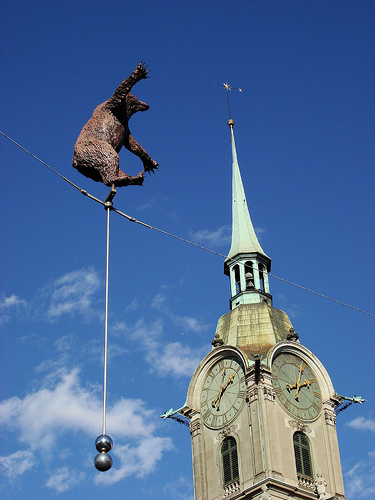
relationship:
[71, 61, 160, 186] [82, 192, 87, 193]
bear statue on wire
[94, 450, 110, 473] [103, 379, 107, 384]
ball on rod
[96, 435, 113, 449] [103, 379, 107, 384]
ball on rod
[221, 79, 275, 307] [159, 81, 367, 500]
steeple of building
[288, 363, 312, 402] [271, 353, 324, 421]
hands of clock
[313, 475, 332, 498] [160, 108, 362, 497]
statue on building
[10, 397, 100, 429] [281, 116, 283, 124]
clouds in sky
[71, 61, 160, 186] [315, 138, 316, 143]
bear statue in air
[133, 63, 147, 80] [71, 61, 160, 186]
bear paw on bear statue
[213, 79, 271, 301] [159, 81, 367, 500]
steeple on building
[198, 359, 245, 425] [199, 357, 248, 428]
numerals on clock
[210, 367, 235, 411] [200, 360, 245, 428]
hands on face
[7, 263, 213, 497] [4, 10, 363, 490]
clouds in sky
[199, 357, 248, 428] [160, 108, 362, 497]
clock on building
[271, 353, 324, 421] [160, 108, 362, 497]
clock on building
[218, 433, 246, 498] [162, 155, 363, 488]
window on building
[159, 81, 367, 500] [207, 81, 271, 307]
building with steeple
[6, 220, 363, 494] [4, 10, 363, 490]
clouds in sky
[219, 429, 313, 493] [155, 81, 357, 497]
windows on tower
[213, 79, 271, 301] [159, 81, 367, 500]
steeple of building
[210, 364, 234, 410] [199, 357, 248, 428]
hands of clock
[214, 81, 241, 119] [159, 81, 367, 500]
cross on top building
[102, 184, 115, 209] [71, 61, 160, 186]
base of bear statue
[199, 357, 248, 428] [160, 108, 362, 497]
clock on side building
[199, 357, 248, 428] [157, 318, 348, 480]
clock on tower